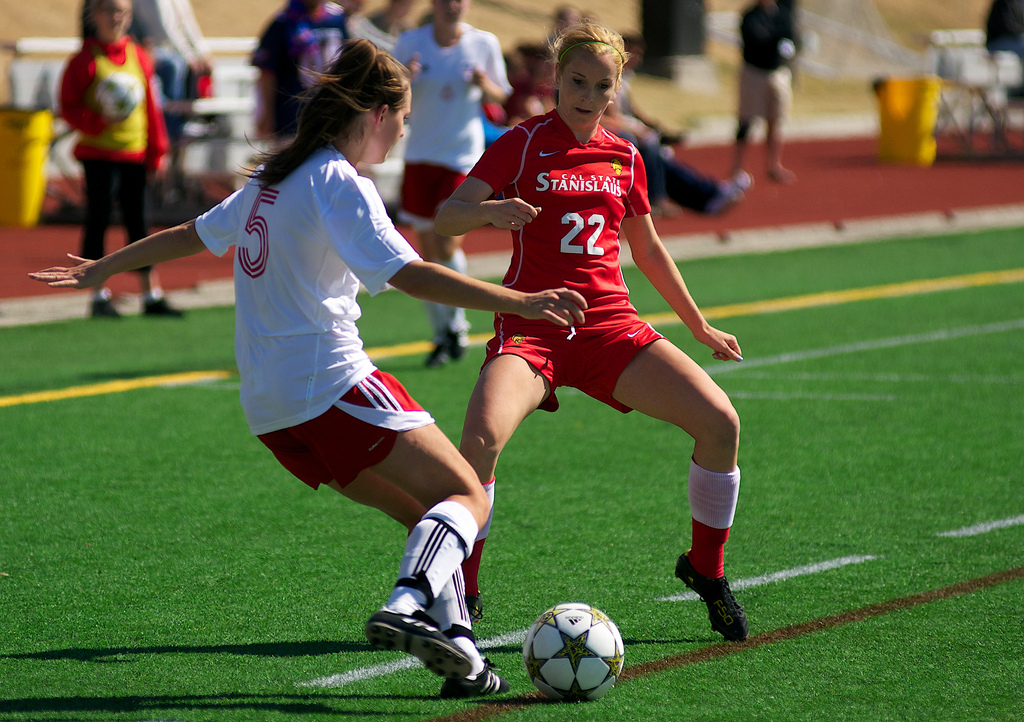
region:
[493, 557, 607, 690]
Soccer ball on the field.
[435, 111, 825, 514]
Girl in a red uniform.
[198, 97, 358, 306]
Five on the shirt.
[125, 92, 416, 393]
White shirt with red five.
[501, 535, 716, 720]
White soccer ball on the field.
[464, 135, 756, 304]
Logo on the shirt.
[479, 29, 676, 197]
Woman with blonde hair.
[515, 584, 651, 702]
a white ball with black stars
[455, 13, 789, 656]
a player in red with white accents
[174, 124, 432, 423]
a white shirt with a red 5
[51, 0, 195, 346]
a person standing holding another ball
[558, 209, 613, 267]
number 22 on her shirt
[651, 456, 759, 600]
a white and red knee high sock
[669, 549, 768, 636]
a solid black shoe on her foot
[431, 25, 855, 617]
A person wearing a red shirt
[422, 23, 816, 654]
A blonde haired woman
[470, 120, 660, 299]
The red shirt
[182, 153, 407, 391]
A white shirt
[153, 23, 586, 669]
A girl with brunette hair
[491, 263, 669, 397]
The red pants without stripes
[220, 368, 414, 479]
A pair of red striped pants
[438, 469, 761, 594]
The red and white socks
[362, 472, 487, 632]
A pair of white socks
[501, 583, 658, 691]
The white soccer ball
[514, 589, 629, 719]
A soccerball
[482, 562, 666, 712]
ball on the ground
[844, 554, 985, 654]
red line on ground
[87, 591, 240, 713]
shadow on the ground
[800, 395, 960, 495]
green grass on ground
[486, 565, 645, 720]
design on the ball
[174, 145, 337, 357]
number on the shirt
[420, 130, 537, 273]
arm of the person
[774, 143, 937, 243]
red ground under person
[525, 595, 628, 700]
a star covered soccer ball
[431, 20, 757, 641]
a female soccer player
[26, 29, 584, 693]
a female soccer player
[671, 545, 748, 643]
a black soccer shoe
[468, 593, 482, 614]
a black soccer shoe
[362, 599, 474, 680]
a black soccer shoe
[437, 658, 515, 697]
a black soccer shoe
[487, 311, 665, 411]
a pair of red shorts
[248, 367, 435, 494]
a pair of red and white shorts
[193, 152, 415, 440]
a white player jersey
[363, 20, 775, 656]
A person is playing.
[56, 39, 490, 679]
A person is playing.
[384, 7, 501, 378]
A person is playing.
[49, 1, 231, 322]
A person is standing up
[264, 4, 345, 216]
A person is standing up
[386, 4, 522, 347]
A person is standing up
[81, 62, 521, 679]
A person is standing up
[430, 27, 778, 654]
A person is standing up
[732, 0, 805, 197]
A person is standing up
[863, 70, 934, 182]
A big yellow bin.